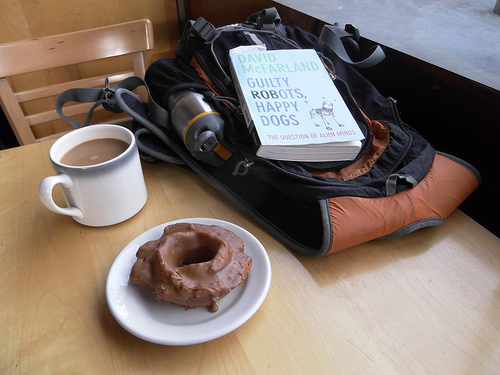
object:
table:
[0, 124, 500, 375]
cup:
[38, 124, 147, 227]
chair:
[0, 19, 155, 145]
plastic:
[165, 87, 226, 135]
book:
[225, 48, 366, 163]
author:
[237, 47, 319, 74]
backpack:
[53, 6, 483, 258]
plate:
[104, 216, 273, 347]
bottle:
[152, 78, 233, 155]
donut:
[128, 222, 253, 313]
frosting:
[157, 218, 212, 249]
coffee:
[59, 138, 131, 167]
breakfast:
[36, 123, 273, 347]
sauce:
[70, 141, 113, 172]